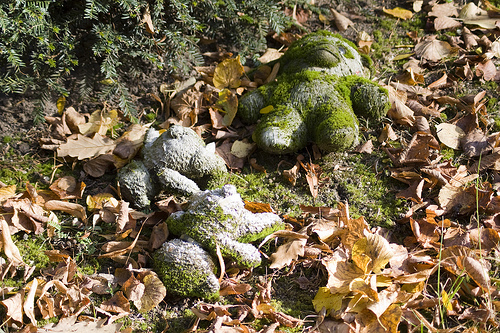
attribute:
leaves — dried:
[4, 7, 498, 328]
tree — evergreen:
[0, 1, 310, 126]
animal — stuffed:
[230, 39, 405, 163]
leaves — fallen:
[384, 99, 496, 240]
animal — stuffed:
[245, 27, 389, 150]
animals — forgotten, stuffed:
[242, 31, 389, 156]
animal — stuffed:
[115, 112, 229, 199]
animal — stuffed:
[148, 182, 286, 302]